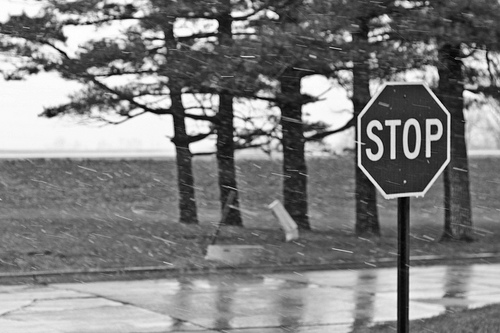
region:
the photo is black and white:
[6, 4, 499, 325]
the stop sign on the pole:
[346, 73, 496, 225]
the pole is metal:
[386, 195, 421, 332]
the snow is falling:
[11, 67, 395, 329]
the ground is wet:
[13, 253, 496, 323]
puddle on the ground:
[196, 273, 314, 300]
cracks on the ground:
[7, 295, 54, 315]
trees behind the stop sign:
[117, 10, 497, 244]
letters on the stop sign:
[371, 117, 444, 158]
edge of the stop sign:
[394, 78, 422, 87]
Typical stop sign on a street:
[353, 78, 453, 201]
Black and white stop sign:
[351, 73, 456, 330]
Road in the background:
[6, 269, 494, 330]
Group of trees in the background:
[0, 3, 498, 219]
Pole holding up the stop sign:
[394, 198, 410, 330]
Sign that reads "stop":
[365, 115, 444, 160]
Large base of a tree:
[442, 12, 469, 237]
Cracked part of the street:
[0, 275, 216, 328]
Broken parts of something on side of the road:
[190, 188, 306, 275]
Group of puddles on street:
[105, 272, 352, 325]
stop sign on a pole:
[350, 81, 450, 331]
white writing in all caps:
[366, 117, 446, 167]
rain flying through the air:
[3, 5, 498, 332]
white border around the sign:
[355, 80, 459, 202]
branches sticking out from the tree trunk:
[0, 21, 167, 121]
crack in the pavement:
[6, 285, 101, 326]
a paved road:
[3, 267, 498, 329]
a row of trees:
[1, 1, 499, 247]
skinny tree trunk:
[161, 86, 214, 225]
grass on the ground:
[0, 155, 497, 272]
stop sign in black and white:
[355, 81, 450, 199]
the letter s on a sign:
[363, 119, 386, 162]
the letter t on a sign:
[382, 117, 402, 158]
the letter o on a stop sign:
[403, 118, 419, 158]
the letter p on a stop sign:
[424, 117, 442, 158]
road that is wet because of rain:
[0, 254, 497, 331]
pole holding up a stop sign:
[395, 196, 409, 330]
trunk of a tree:
[277, 52, 309, 233]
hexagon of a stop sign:
[357, 82, 450, 199]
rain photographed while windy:
[450, 163, 475, 175]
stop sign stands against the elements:
[353, 78, 448, 330]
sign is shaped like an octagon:
[352, 76, 452, 203]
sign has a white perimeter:
[355, 80, 452, 200]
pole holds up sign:
[392, 194, 412, 330]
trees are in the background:
[0, 4, 497, 239]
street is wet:
[0, 255, 497, 331]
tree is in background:
[1, 2, 237, 224]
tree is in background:
[163, 0, 290, 222]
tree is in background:
[227, 0, 345, 230]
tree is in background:
[402, 1, 499, 235]